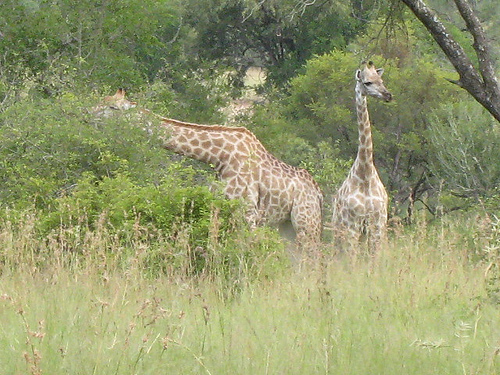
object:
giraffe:
[92, 89, 326, 267]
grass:
[0, 198, 500, 375]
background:
[0, 1, 500, 219]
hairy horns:
[361, 60, 375, 70]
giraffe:
[331, 60, 394, 264]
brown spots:
[224, 138, 259, 172]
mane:
[131, 101, 248, 133]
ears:
[355, 67, 385, 82]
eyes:
[363, 82, 372, 87]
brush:
[0, 76, 177, 216]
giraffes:
[84, 61, 392, 273]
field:
[0, 0, 500, 375]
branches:
[404, 0, 500, 122]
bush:
[37, 150, 290, 307]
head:
[355, 61, 393, 103]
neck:
[131, 106, 240, 170]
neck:
[349, 96, 381, 183]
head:
[88, 88, 137, 119]